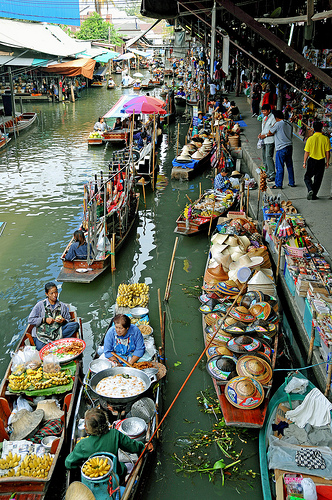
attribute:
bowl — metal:
[88, 360, 151, 406]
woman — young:
[63, 227, 95, 263]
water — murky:
[13, 144, 100, 233]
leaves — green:
[182, 428, 263, 467]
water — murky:
[3, 94, 211, 308]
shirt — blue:
[102, 326, 144, 357]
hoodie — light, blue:
[96, 305, 156, 364]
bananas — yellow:
[5, 366, 73, 390]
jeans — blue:
[274, 143, 295, 187]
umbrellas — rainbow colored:
[113, 70, 172, 139]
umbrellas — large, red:
[118, 93, 168, 116]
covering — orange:
[46, 54, 96, 81]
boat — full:
[200, 210, 280, 429]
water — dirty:
[18, 105, 196, 493]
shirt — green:
[27, 297, 71, 343]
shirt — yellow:
[304, 131, 330, 159]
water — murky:
[9, 77, 292, 498]